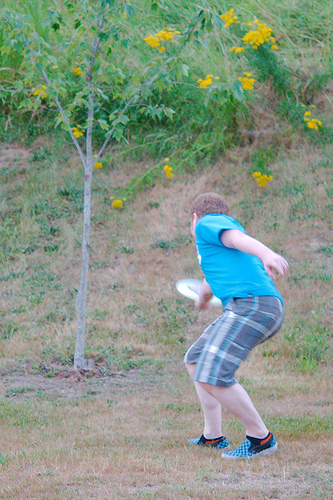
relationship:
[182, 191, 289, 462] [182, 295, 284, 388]
boy wearing shorts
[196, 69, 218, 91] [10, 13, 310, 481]
flower in field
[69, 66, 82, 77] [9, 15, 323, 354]
flower in field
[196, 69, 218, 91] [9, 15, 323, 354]
flower in field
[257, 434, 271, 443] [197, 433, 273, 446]
stripe on socks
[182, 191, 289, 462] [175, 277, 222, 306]
boy catching frisbee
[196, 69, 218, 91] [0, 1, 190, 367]
flower on tree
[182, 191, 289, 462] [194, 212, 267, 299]
boy wearing a shirt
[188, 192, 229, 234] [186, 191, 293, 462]
head of a boy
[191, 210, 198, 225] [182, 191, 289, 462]
ear of a boy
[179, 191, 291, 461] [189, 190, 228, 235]
hair of a boy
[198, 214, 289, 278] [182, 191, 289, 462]
arm of a boy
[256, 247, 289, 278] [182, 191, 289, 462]
hand of a boy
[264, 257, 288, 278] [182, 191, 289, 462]
fingers of a boy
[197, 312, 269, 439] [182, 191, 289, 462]
leg of a boy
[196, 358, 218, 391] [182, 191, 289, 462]
knee of a boy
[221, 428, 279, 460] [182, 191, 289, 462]
foot of a boy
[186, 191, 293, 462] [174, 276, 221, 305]
boy catching frisbee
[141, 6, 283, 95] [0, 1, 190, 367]
blossoms on tree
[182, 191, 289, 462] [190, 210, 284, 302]
boy wearing shirt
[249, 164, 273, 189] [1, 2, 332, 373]
flower on trees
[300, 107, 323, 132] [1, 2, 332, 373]
flower on trees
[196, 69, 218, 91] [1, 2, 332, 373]
flower on trees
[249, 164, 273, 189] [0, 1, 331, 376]
flower on tree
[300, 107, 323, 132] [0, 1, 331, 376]
flower on tree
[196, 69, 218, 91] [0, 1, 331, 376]
flower on tree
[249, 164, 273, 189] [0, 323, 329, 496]
flower on field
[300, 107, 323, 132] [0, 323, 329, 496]
flower on field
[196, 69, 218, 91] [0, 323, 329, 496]
flower on field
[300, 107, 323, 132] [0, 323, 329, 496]
flower in field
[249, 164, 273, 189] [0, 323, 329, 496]
flower in field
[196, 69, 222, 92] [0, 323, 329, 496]
flower in field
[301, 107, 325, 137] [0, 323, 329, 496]
flower in field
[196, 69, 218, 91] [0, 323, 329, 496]
flower in field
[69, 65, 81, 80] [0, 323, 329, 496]
flower in field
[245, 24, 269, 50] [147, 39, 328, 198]
flower in field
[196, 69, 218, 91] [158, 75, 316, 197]
flower in field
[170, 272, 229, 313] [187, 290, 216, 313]
frisbee in man's hand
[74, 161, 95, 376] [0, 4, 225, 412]
trunk of tree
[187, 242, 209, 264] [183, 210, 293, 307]
emblem on shirt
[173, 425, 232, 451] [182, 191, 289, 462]
shoe on boy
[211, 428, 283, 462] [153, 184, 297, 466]
shoe on man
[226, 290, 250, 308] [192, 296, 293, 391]
pocket of shorts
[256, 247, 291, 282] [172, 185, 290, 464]
hand of man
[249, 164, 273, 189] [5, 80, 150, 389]
flower on tree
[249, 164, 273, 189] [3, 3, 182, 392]
flower on tree